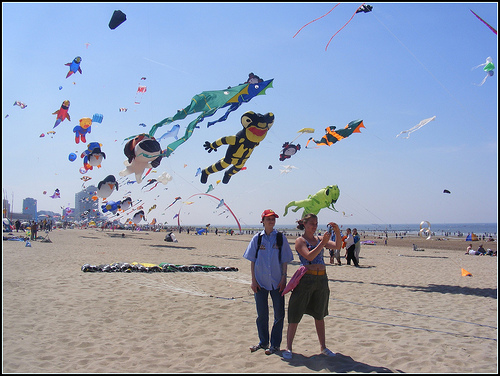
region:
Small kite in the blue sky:
[390, 105, 457, 159]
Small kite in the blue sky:
[437, 181, 471, 213]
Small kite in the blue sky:
[471, 54, 498, 80]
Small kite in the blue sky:
[99, 6, 143, 34]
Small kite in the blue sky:
[54, 52, 90, 82]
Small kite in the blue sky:
[43, 94, 78, 125]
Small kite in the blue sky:
[65, 109, 94, 156]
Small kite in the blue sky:
[78, 146, 118, 161]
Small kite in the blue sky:
[108, 122, 161, 183]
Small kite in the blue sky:
[97, 171, 143, 206]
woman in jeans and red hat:
[242, 208, 292, 355]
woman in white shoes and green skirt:
[283, 213, 340, 362]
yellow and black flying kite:
[195, 110, 272, 184]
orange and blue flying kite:
[305, 118, 367, 145]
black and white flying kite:
[120, 133, 162, 185]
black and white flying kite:
[85, 145, 107, 169]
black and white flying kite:
[92, 175, 118, 205]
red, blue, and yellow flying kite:
[73, 118, 90, 144]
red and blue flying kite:
[51, 100, 71, 129]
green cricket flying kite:
[282, 183, 341, 216]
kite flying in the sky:
[182, 67, 291, 137]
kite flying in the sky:
[268, 116, 310, 179]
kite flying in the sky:
[300, 111, 366, 156]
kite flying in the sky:
[287, 171, 362, 231]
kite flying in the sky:
[119, 120, 166, 188]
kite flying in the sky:
[96, 169, 131, 212]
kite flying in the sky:
[66, 112, 123, 147]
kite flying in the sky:
[47, 95, 77, 137]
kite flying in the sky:
[62, 45, 94, 82]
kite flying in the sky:
[98, 8, 142, 33]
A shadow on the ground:
[266, 349, 402, 375]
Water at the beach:
[223, 224, 495, 234]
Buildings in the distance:
[1, 186, 98, 217]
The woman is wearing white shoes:
[282, 347, 334, 357]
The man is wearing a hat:
[261, 209, 278, 218]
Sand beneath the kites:
[0, 229, 498, 373]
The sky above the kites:
[0, 3, 497, 223]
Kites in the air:
[1, 2, 494, 227]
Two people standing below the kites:
[247, 210, 344, 357]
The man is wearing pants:
[254, 287, 284, 346]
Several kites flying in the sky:
[37, 34, 360, 175]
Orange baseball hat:
[254, 206, 281, 238]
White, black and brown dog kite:
[121, 130, 165, 172]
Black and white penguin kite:
[93, 173, 120, 203]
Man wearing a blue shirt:
[243, 209, 291, 290]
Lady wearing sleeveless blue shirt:
[294, 233, 327, 267]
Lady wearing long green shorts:
[289, 265, 334, 327]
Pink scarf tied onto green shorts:
[280, 263, 330, 295]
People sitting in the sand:
[461, 239, 498, 256]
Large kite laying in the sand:
[79, 255, 245, 284]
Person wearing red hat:
[243, 208, 295, 355]